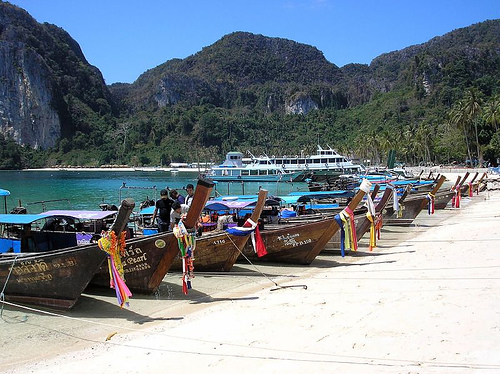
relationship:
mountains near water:
[143, 14, 382, 151] [3, 154, 170, 231]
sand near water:
[2, 160, 499, 371] [8, 164, 442, 266]